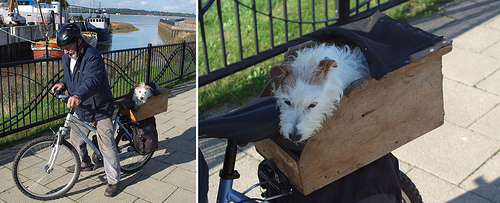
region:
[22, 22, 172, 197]
the man is riding a bike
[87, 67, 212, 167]
the dog is in a box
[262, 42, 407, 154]
the dog's ears are brown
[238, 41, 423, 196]
the dog is white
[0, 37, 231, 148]
the railings are black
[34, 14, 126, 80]
the man is wearing a helmet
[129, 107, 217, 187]
shadow on the ground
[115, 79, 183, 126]
the dog is behind the man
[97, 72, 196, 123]
the box is made of wood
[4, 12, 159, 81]
the boats on the water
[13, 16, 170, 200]
man on bicycle with dog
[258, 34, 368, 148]
closeup of dog in basket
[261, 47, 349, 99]
white dog with brown ears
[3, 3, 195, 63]
ocean in the background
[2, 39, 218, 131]
black fence along sidewalk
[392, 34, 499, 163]
stone tiled sidewalk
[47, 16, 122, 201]
man wearing bicycle helmet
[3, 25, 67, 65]
boat docked in inlet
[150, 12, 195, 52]
walled section along water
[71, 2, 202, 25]
shore line in distance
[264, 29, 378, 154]
a small brown and white dog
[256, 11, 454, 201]
a wooden carrier on the back of a bike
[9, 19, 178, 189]
a man riding a bike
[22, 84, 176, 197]
a silver and black bike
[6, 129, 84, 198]
a black bike tire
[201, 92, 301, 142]
a black bicycle seat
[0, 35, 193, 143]
a black iron fence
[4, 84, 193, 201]
a concrete tile paved walkway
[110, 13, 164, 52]
pretty blue water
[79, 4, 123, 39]
a boat on the water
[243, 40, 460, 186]
a dog that looks scared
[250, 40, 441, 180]
a dog sitting in a box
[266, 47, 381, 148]
a white dog with a lot of hair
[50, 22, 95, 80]
a man wearing a black helmet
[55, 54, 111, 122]
a navy colored jacket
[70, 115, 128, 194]
a pair of khaki pants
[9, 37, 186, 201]
a man taking his dog for a ride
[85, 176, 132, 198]
a pair of brown shoes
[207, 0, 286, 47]
a black iron fence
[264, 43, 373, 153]
small white and brown dog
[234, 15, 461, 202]
wooden carrying basket with dog inside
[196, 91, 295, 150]
black bicycle seat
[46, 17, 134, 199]
middle aged man wearing a helmet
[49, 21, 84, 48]
black helmet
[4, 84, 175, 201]
silver bicycle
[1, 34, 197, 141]
black iron fence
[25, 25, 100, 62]
red boat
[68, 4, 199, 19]
land on the other side of the river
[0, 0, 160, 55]
river with boats in it